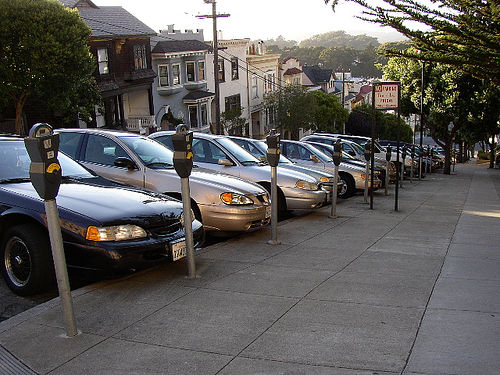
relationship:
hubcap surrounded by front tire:
[4, 235, 30, 287] [0, 216, 49, 297]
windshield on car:
[209, 132, 271, 167] [159, 128, 330, 218]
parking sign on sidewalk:
[372, 81, 406, 108] [1, 147, 492, 373]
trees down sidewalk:
[323, 0, 498, 177] [1, 147, 492, 373]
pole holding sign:
[368, 78, 378, 213] [370, 80, 398, 111]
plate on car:
[169, 230, 194, 265] [8, 131, 239, 305]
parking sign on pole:
[371, 81, 400, 111] [368, 110, 403, 207]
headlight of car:
[213, 179, 271, 217] [14, 133, 205, 280]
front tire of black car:
[2, 218, 51, 297] [190, 206, 205, 253]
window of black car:
[1, 139, 96, 183] [0, 133, 205, 297]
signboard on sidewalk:
[367, 82, 407, 110] [1, 147, 492, 373]